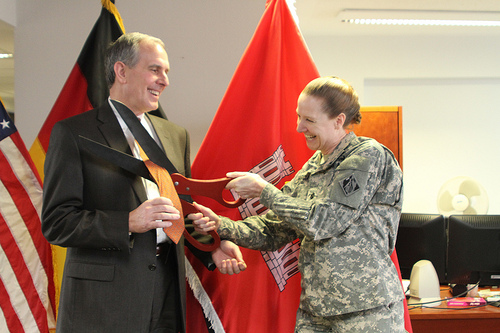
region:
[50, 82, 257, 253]
Giant scissors cutting a tie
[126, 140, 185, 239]
Orange tie in a person's hand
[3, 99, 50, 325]
American flag hanging on a pole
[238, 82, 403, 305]
Military uniform on a woman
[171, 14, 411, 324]
Red flag in the background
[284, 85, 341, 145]
Woman smiling at a man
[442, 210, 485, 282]
Black leather chair in background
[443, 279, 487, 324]
Wooden desk with stuff on it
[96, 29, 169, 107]
Gray hair on a man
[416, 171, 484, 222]
White fan in the background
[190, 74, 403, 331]
A woman in camouflage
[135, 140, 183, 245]
A man's orange neck tie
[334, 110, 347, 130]
A woman's left ear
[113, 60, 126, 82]
A man's right ear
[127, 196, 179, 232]
A man's right hand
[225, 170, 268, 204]
A woman's left hand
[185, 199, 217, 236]
A woman's right hand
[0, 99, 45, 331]
A United States flag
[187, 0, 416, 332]
A big red flag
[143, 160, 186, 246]
the tie in the mans hand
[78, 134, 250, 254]
the giant pair of scissors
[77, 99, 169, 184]
the blades of the scissors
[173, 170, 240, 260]
the red handles of the scissors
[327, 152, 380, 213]
the patch on the womensuniform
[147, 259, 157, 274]
the button on the jacket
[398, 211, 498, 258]
the black moniters on the desk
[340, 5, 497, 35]
the lights opn the wall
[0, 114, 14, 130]
the star on the flag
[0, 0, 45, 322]
the flags behind the people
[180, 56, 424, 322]
a woman cutting with big scissors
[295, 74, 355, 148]
the head of a woman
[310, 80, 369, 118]
the hair of a woman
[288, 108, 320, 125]
the eyes of a woman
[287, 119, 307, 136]
the nose of a woman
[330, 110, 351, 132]
the ear of a woman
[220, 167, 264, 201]
the left hand of a woman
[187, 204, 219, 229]
the right hand of a woman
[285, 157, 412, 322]
an army woman's uniform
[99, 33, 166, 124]
the head of a man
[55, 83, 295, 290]
a large pair of scissors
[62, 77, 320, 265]
the scissors require two hands to use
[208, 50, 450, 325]
she is wearing a uniform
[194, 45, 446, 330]
she is wearing an army uniform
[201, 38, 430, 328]
the woman is in the military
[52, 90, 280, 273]
a pair of novelty scissors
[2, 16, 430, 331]
she is cutting the man's tie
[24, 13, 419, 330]
she is playfully cutting his tie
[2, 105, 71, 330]
the American flag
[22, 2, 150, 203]
this is the German flag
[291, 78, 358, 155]
woman with a big smile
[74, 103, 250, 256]
very large scissors with red handle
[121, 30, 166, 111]
man laughing at the woman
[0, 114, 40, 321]
part of the American flag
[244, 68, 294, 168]
large red flag behind the woman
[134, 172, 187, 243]
man holding his tie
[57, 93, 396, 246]
woman cutting man's tie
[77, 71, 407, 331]
military woman holding large scissors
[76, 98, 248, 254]
oversized scissors with red handle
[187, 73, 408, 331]
woman wearing military uniform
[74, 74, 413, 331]
woman cutting a man's tie